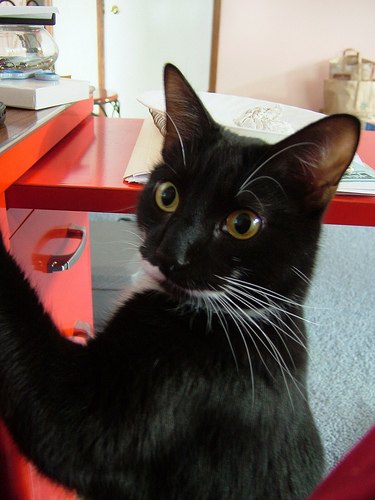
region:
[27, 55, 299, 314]
this is a cat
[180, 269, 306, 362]
the cat has long whiskers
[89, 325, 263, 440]
this is a black cat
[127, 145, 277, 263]
the cats eyes are wide open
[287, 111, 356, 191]
the inside of the cats ears are pink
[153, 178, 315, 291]
the cat's eyes are yellow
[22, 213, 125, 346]
this is a dresser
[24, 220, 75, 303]
the dresser is red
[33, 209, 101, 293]
the handle is metal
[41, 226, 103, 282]
the handle is gray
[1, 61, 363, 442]
the cat beside the desk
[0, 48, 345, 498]
the cat is black and white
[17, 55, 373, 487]
the cat is curious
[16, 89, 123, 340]
the desk is red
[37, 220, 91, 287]
the handle of the drawer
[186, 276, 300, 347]
whiskers on the cat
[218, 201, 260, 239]
the eye of the cat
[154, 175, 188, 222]
the eye of the cat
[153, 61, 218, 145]
ear of the cat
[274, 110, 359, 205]
ear of the cat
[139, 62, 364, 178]
cat has black ears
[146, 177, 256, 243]
cat has green eyes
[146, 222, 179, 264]
cat has black nose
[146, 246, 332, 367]
cat has white whiskers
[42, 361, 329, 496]
cat has black fur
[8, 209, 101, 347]
red drawer under desk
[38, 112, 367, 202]
red and sliding desk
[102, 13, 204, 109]
white door behind cat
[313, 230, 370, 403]
light blue carpet under cat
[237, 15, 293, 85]
pink wall near door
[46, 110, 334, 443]
cat is climbing on the table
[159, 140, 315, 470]
cat is staring in the open air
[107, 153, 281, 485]
cat is black in color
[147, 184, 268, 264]
the eyes are brown black in color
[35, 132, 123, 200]
the table is red in color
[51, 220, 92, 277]
the handls are silvery in color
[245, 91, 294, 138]
the plate is white in color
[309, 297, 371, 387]
the floor has a white carpet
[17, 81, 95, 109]
the box is white in color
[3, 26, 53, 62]
the bottle is colorles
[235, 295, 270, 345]
part f a whisker